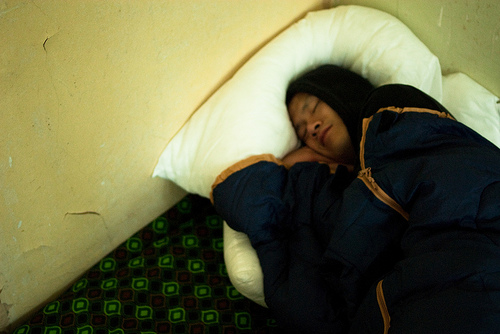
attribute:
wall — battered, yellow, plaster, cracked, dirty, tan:
[0, 1, 329, 334]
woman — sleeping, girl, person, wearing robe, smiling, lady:
[212, 66, 499, 334]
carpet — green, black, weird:
[0, 193, 277, 333]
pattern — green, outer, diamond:
[153, 215, 168, 233]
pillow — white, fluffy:
[152, 6, 443, 200]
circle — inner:
[155, 220, 164, 230]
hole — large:
[65, 206, 105, 223]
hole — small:
[42, 32, 56, 54]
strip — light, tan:
[210, 153, 279, 204]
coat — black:
[212, 86, 499, 331]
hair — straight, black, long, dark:
[285, 65, 376, 151]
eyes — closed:
[300, 102, 319, 139]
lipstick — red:
[319, 124, 333, 145]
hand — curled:
[286, 146, 335, 167]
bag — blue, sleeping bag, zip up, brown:
[210, 106, 500, 333]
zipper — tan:
[357, 167, 384, 197]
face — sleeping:
[286, 93, 351, 159]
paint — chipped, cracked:
[34, 31, 114, 101]